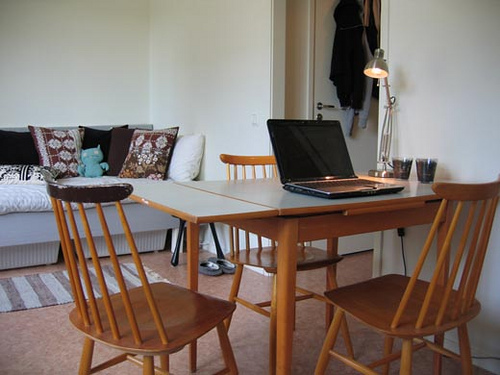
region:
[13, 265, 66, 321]
small blue and gray runner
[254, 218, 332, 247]
wood base on table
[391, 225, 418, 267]
black electrical cord on wall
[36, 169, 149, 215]
shiny black top on chair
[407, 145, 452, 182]
shiny black cup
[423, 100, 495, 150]
blue paint on the wall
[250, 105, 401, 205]
black lap top on table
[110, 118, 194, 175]
brown pillow with flower design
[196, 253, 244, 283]
pair of gray slippers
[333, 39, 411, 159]
table lamp on top of table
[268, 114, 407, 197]
Black laptop sitting open on table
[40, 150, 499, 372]
Three wooden chairs around a wooden table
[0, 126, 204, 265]
White couch with brown, white, and black throw pillows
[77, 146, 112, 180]
Blue stuffed animal on couch surrounded by throw pillows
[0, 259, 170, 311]
Striped rug on floor in front of couch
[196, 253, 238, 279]
Bedroom slippers next to white wall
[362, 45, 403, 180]
Tall silver desk lamp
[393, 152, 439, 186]
Two brown cups on edge of table next to wall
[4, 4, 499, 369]
Living/dining room with blank white walls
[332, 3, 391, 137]
Sweatshirts and coats hanging on door hook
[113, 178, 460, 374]
a wood table in a living room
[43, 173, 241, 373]
a wooden chair with a black top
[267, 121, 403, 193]
a black laptop on a table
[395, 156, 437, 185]
two glasses of soda on a table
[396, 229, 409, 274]
a black wire on the wall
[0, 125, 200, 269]
a gray sofa in a living room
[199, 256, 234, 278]
a pair of gray slippers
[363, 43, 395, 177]
a desk lamp on a table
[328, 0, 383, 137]
coats hanging on a door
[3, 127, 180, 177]
various cushions on a sofa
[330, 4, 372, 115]
coats hanging on door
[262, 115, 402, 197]
Laptop sitting on table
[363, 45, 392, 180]
Working table lamp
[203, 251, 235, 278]
pair of slippers on floor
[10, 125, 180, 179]
Throw pillows on couch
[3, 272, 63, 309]
Tan and white area rug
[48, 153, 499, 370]
table with three chairs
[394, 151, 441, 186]
2 cups sitting on table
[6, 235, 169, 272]
two storage containers under couch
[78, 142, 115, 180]
blue stuffed animal on couch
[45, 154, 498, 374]
A dining room table set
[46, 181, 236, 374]
A wooden dining chair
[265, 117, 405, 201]
A laptop computer that is off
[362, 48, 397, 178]
A metal desk lamp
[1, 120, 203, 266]
Part of a couch full of pillows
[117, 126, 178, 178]
A brown and white floral pillow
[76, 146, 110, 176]
A light blue stuffed animal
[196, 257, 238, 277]
A pair of gray slippers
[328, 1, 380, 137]
Some jackets hanging up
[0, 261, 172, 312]
A dark and light gray stripped rug